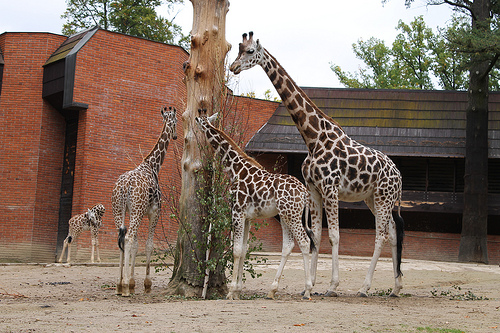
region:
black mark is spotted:
[47, 297, 53, 314]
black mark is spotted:
[39, 302, 54, 324]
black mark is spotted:
[41, 301, 51, 313]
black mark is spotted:
[42, 300, 58, 317]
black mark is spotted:
[50, 297, 56, 314]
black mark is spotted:
[33, 295, 48, 312]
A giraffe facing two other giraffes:
[108, 102, 179, 300]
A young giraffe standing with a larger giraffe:
[191, 102, 322, 309]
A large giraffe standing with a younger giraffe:
[229, 30, 414, 305]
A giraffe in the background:
[54, 202, 107, 270]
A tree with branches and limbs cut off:
[161, 0, 241, 305]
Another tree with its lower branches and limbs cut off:
[452, 0, 488, 272]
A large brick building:
[1, 31, 266, 253]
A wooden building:
[256, 90, 496, 232]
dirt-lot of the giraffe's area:
[1, 265, 494, 332]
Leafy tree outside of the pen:
[327, 2, 499, 85]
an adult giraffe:
[230, 31, 403, 297]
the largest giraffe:
[230, 31, 402, 300]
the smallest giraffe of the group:
[55, 204, 106, 266]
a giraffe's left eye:
[245, 46, 254, 54]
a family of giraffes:
[58, 32, 402, 299]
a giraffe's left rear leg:
[280, 210, 316, 299]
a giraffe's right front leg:
[145, 199, 164, 296]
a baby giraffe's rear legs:
[58, 218, 77, 261]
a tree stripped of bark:
[168, 0, 233, 295]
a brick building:
[2, 28, 499, 260]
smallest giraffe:
[51, 200, 106, 267]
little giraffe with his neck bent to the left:
[48, 198, 105, 267]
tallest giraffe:
[229, 26, 414, 303]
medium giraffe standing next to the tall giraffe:
[187, 102, 319, 299]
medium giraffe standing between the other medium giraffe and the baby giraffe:
[107, 89, 178, 294]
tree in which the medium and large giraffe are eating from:
[172, 0, 231, 302]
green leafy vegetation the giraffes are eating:
[181, 124, 243, 288]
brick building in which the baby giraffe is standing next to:
[88, 47, 210, 232]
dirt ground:
[31, 280, 438, 326]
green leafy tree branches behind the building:
[347, 45, 453, 79]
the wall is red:
[113, 64, 208, 184]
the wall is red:
[96, 75, 237, 235]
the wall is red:
[81, 92, 171, 167]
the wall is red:
[50, 20, 205, 155]